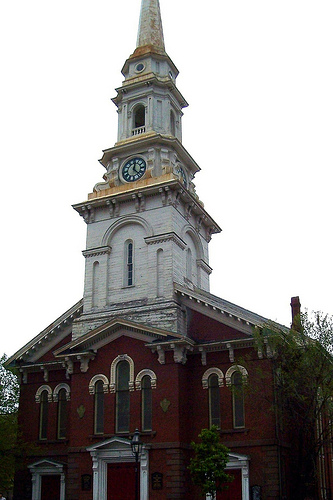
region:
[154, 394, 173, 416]
Brass PLate on brick building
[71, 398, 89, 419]
Brass PLate on brick building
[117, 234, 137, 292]
Slim long window of building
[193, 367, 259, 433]
Two long windows on brick building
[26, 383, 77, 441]
Two long windows on brick building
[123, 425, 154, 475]
Black lamp post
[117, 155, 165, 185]
Blue faced clock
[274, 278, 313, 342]
Brick chimney on building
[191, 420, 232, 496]
Small green tree with leaves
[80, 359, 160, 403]
Lovely detail on brick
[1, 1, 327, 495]
a red brick church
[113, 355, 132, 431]
a tall church window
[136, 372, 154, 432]
a tall church window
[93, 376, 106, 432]
a tall church window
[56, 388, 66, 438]
a tall church window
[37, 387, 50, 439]
a tall church window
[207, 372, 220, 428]
a tall church window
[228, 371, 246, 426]
a tall church window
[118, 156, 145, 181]
a black and white clock face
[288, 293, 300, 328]
a brick chimney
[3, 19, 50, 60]
white clouds against blue sky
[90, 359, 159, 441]
gold windows in red building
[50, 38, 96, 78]
white clouds against blue sky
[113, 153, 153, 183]
clock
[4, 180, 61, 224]
white clouds against blue sky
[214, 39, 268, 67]
white clouds against blue sky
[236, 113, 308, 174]
white clouds against blue sky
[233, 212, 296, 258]
white clouds against blue sky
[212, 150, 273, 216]
white clouds against blue sky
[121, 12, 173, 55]
steeple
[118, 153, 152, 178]
black and white clock in clock tower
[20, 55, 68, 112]
white clouds against blue sky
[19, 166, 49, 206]
white clouds against blue sky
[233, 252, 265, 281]
white clouds against blue sky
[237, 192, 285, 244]
white clouds against blue sky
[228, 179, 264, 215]
white clouds against blue sky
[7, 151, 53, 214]
white clouds against blue sky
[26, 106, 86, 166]
white clouds against blue sky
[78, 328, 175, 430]
red and gold windows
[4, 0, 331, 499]
A very old red and white building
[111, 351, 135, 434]
a tall arched window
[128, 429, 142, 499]
a black lamp not turned on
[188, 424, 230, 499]
a baby tree with green leafs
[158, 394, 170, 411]
a wall sconce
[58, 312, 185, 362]
a pointed rood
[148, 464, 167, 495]
a black plaque with words on it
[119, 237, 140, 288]
a very slim and narrow window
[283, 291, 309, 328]
a tall red brick fireplace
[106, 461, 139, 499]
a red entry door